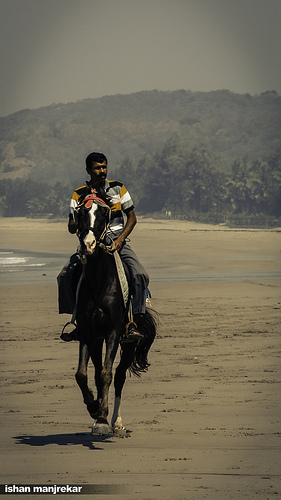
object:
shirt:
[68, 177, 136, 245]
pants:
[104, 230, 151, 315]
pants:
[57, 245, 88, 324]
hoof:
[92, 416, 110, 435]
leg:
[74, 332, 102, 419]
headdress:
[74, 188, 112, 221]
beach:
[0, 217, 280, 499]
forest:
[0, 87, 281, 226]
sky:
[0, 0, 280, 116]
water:
[0, 250, 11, 265]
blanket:
[106, 234, 134, 322]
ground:
[175, 296, 220, 425]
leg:
[93, 328, 120, 437]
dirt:
[0, 215, 281, 500]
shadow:
[11, 426, 134, 450]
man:
[56, 152, 151, 343]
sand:
[0, 218, 280, 499]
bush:
[218, 154, 279, 216]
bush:
[127, 142, 206, 211]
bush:
[0, 176, 72, 220]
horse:
[67, 187, 165, 436]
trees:
[45, 176, 70, 214]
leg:
[90, 337, 103, 403]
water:
[33, 262, 45, 267]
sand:
[0, 248, 48, 266]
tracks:
[112, 360, 225, 439]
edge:
[0, 212, 281, 229]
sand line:
[1, 245, 272, 280]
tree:
[159, 130, 181, 163]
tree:
[230, 155, 243, 180]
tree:
[146, 140, 159, 176]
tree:
[118, 152, 133, 177]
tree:
[11, 126, 37, 153]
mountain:
[0, 88, 281, 229]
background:
[0, 0, 281, 223]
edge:
[99, 415, 107, 418]